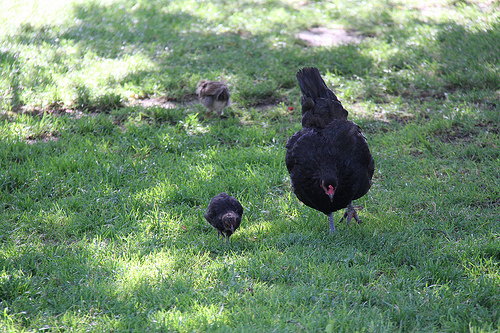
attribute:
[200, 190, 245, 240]
chicken — baby, black, brown, family, walking, little, eating, small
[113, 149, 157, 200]
grass — green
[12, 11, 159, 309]
yard — grassy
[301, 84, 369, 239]
chicken — large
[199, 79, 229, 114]
bird — baby, brown